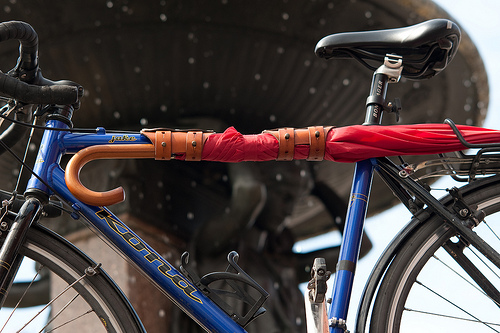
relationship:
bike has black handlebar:
[2, 17, 499, 330] [0, 17, 83, 113]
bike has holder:
[2, 17, 499, 330] [171, 245, 273, 325]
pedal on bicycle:
[194, 230, 251, 292] [56, 74, 468, 331]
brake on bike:
[440, 184, 484, 230] [2, 17, 499, 330]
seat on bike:
[298, 13, 468, 83] [2, 17, 499, 330]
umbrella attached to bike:
[64, 117, 499, 207] [2, 17, 499, 330]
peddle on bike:
[311, 256, 333, 303] [2, 17, 499, 330]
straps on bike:
[266, 127, 333, 161] [2, 17, 499, 330]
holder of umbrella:
[63, 143, 155, 207] [64, 117, 499, 207]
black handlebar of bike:
[0, 17, 83, 113] [2, 17, 499, 330]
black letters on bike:
[89, 204, 209, 306] [2, 17, 499, 330]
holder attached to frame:
[171, 245, 273, 325] [21, 112, 489, 331]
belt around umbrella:
[151, 127, 335, 166] [81, 109, 498, 184]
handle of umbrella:
[63, 140, 158, 202] [64, 117, 499, 207]